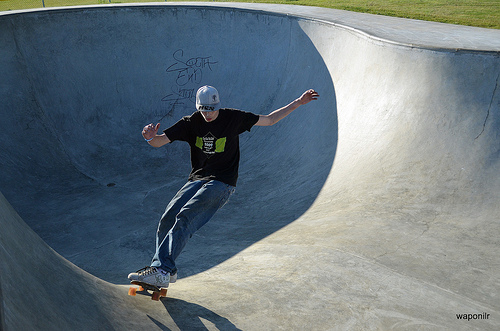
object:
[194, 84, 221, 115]
cap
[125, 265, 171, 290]
shoes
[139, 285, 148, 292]
wheel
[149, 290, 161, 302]
wheel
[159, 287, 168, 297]
wheel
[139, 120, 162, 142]
hand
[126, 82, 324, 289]
boy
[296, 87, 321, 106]
hand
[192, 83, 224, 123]
head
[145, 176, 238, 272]
jeans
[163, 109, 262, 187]
shirt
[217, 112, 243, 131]
black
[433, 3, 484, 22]
green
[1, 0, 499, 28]
field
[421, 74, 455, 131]
gray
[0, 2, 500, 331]
park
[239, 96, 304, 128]
arm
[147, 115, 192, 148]
arms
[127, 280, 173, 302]
skateboard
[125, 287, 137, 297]
wheels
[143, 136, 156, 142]
bracelet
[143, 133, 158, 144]
wrist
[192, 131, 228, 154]
design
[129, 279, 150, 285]
tip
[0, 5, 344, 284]
shadow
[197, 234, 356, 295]
ground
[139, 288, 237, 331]
shadow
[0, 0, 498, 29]
grass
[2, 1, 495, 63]
background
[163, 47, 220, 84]
graffiti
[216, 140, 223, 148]
green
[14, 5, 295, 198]
ramp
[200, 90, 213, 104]
grey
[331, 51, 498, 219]
wall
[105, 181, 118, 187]
drain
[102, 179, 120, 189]
water